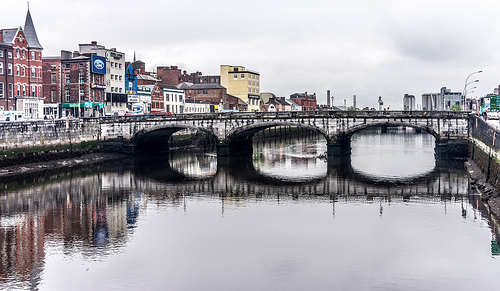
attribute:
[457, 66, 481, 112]
lights — Street 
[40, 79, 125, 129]
people — walking.  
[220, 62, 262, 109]
yellow building — tall , square 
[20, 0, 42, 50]
roof — pointed 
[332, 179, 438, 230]
river — part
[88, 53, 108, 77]
sign — Blue 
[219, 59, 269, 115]
building — Cream colored 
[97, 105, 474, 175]
bridge — part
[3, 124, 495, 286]
water — body , calm , shiny 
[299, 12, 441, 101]
sky — cloudy , hazy 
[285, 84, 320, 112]
house — part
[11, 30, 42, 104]
building — red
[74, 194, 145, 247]
reflection — part